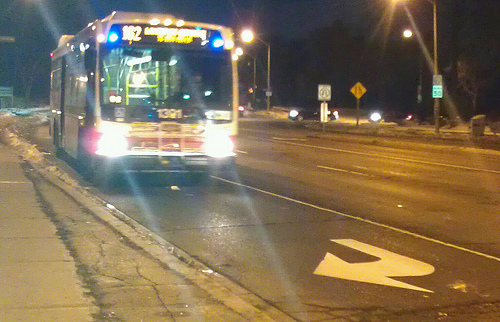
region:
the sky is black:
[278, 7, 365, 27]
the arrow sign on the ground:
[278, 196, 413, 319]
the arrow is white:
[296, 210, 462, 311]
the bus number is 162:
[96, 15, 248, 95]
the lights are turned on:
[58, 115, 310, 194]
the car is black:
[279, 95, 364, 155]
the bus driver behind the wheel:
[153, 55, 258, 140]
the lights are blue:
[85, 25, 280, 70]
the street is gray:
[183, 195, 322, 309]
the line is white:
[254, 172, 391, 229]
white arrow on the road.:
[311, 227, 406, 291]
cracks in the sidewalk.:
[97, 249, 164, 303]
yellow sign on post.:
[351, 80, 367, 94]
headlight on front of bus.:
[207, 130, 230, 164]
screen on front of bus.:
[120, 27, 207, 39]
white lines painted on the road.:
[303, 167, 379, 181]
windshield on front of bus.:
[109, 67, 199, 79]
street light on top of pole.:
[242, 10, 267, 43]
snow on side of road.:
[10, 112, 30, 162]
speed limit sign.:
[425, 82, 448, 100]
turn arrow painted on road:
[248, 203, 441, 319]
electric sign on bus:
[110, 18, 225, 46]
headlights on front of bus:
[89, 119, 246, 163]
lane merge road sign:
[346, 76, 373, 103]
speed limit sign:
[429, 76, 451, 104]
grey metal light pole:
[260, 45, 275, 110]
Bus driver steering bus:
[167, 66, 225, 108]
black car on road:
[276, 103, 346, 123]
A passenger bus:
[34, 9, 242, 182]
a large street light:
[238, 19, 260, 53]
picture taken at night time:
[45, 10, 457, 293]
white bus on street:
[44, 3, 270, 198]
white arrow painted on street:
[290, 208, 447, 301]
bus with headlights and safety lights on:
[60, 13, 260, 206]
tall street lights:
[244, 16, 283, 114]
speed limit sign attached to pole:
[427, 80, 449, 107]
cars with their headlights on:
[268, 101, 422, 132]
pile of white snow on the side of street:
[7, 93, 50, 167]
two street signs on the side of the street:
[307, 66, 372, 133]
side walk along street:
[10, 168, 107, 313]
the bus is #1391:
[40, 6, 267, 207]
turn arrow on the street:
[264, 191, 449, 309]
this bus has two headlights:
[7, 5, 327, 227]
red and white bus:
[28, 12, 293, 212]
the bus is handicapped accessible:
[96, 85, 140, 140]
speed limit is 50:
[410, 52, 475, 147]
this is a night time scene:
[35, 25, 363, 241]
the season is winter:
[261, 46, 489, 171]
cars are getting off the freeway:
[279, 55, 497, 192]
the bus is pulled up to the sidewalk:
[11, 25, 261, 253]